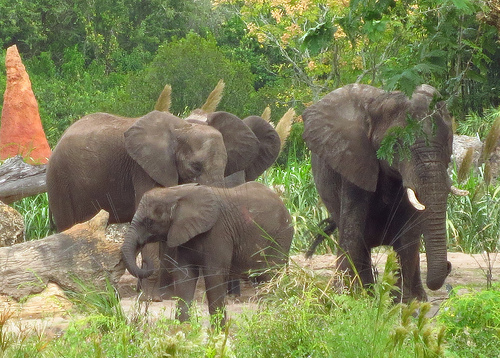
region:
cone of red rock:
[0, 40, 50, 157]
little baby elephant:
[117, 185, 294, 323]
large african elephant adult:
[290, 82, 455, 308]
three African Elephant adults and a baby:
[42, 81, 452, 323]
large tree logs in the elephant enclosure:
[2, 212, 497, 337]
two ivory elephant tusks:
[398, 177, 475, 215]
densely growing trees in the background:
[0, 2, 499, 172]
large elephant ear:
[295, 86, 381, 191]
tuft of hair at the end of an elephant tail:
[300, 207, 337, 257]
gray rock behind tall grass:
[447, 129, 499, 189]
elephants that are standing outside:
[72, 68, 472, 325]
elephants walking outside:
[66, 69, 415, 343]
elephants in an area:
[41, 30, 496, 346]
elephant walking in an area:
[57, 75, 490, 335]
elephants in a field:
[104, 83, 465, 333]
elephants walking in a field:
[119, 96, 454, 351]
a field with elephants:
[87, 36, 414, 343]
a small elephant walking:
[112, 176, 300, 355]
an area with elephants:
[11, 66, 460, 351]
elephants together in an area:
[68, 45, 460, 347]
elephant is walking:
[304, 80, 456, 304]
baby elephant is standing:
[117, 179, 294, 326]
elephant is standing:
[42, 110, 227, 244]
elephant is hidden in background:
[202, 107, 282, 181]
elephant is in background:
[47, 110, 227, 234]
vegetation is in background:
[0, 0, 497, 247]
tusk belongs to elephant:
[401, 183, 422, 211]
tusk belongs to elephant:
[445, 181, 471, 197]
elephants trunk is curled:
[120, 222, 155, 278]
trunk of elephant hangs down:
[416, 168, 450, 292]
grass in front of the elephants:
[30, 283, 488, 356]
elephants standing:
[51, 82, 481, 274]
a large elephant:
[297, 76, 464, 288]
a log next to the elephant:
[6, 225, 158, 286]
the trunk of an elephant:
[400, 131, 461, 275]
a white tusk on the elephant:
[406, 186, 423, 212]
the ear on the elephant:
[121, 105, 187, 177]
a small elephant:
[128, 177, 290, 309]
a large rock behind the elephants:
[6, 51, 43, 147]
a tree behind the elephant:
[278, 54, 343, 103]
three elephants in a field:
[45, 71, 455, 326]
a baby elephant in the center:
[120, 180, 297, 317]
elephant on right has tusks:
[401, 181, 466, 211]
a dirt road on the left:
[0, 42, 60, 185]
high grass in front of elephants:
[2, 276, 497, 356]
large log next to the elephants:
[0, 211, 150, 321]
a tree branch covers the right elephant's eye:
[367, 43, 454, 164]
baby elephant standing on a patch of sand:
[18, 285, 264, 345]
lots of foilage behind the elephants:
[30, 42, 490, 162]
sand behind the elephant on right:
[283, 247, 496, 286]